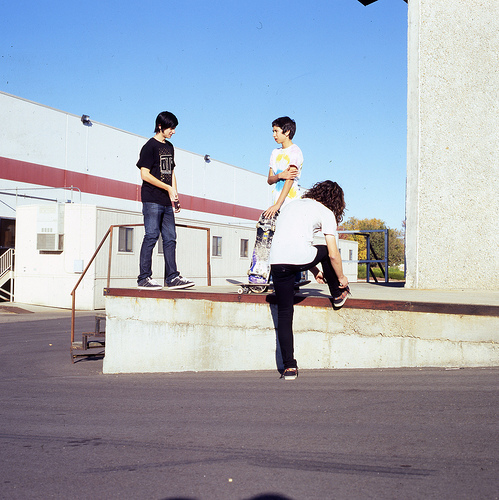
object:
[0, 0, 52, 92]
sky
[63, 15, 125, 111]
sky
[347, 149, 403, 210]
clouds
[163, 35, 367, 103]
sky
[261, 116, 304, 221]
boy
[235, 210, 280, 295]
skateboard